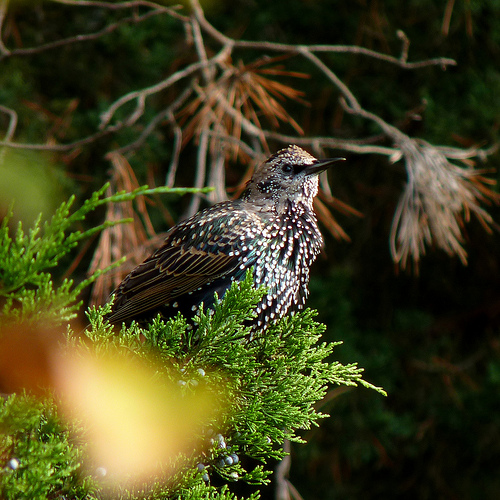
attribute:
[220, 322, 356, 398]
leaves — green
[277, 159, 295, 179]
eye — black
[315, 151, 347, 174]
beak — pointy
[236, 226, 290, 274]
dots — white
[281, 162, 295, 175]
eye — open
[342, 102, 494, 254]
flower — white